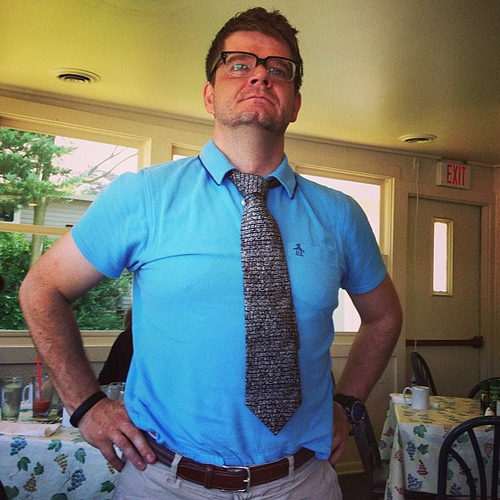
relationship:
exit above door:
[435, 158, 477, 193] [396, 186, 498, 418]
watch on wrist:
[321, 350, 422, 461] [329, 377, 371, 435]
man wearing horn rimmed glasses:
[17, 4, 404, 499] [196, 41, 310, 95]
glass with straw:
[29, 372, 56, 418] [29, 352, 49, 379]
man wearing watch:
[17, 4, 404, 499] [333, 392, 367, 428]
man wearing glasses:
[17, 8, 406, 492] [205, 42, 301, 92]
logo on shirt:
[291, 242, 305, 257] [69, 137, 388, 468]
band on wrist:
[66, 389, 110, 427] [58, 384, 113, 427]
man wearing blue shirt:
[17, 8, 406, 492] [66, 136, 391, 473]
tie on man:
[236, 170, 311, 383] [17, 8, 406, 492]